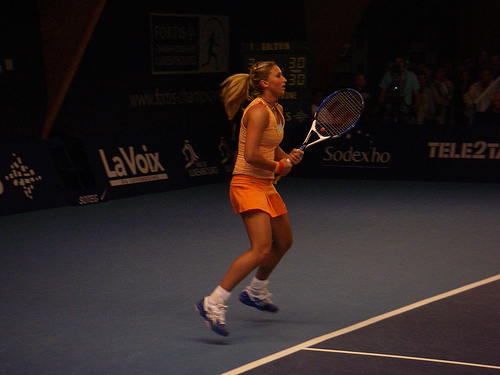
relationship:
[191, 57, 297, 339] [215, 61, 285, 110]
woman has ponytail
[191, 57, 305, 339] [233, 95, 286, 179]
woman wearing shirt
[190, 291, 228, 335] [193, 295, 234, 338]
shoe with shoe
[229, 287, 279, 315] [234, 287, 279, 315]
shoe with shoe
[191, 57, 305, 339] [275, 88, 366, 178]
woman holding tennis racket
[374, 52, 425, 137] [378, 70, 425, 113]
man wearing shirt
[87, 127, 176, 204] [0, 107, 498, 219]
advertisement on wall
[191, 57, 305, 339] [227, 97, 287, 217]
woman wearing tennis outfit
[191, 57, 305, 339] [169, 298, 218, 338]
woman jumping in air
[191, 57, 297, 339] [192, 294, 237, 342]
woman wearing shoe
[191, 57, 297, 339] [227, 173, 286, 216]
woman wearing orange skirt